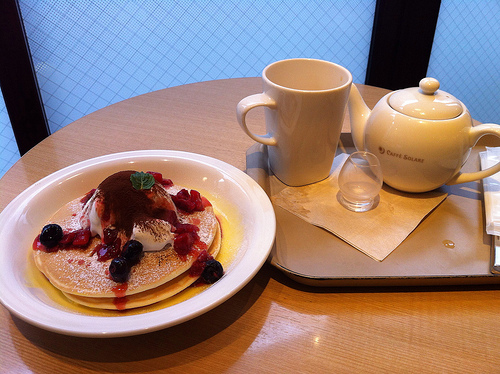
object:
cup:
[236, 58, 352, 186]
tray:
[243, 130, 499, 287]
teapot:
[348, 77, 499, 192]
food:
[29, 170, 245, 317]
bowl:
[0, 149, 276, 338]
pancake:
[30, 186, 219, 310]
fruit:
[198, 252, 208, 261]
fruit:
[108, 258, 130, 282]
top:
[388, 77, 462, 120]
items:
[146, 53, 475, 232]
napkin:
[270, 153, 448, 262]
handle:
[235, 92, 277, 145]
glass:
[337, 151, 384, 213]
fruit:
[121, 239, 143, 260]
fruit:
[73, 233, 89, 245]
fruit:
[40, 224, 63, 249]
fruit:
[171, 188, 203, 211]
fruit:
[173, 233, 194, 255]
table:
[0, 76, 499, 373]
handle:
[447, 123, 500, 186]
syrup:
[32, 170, 210, 310]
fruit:
[202, 259, 224, 285]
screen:
[1, 1, 500, 180]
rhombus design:
[118, 27, 134, 43]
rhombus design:
[190, 20, 203, 35]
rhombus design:
[253, 28, 267, 41]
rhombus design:
[296, 38, 310, 52]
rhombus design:
[165, 47, 179, 61]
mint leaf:
[130, 171, 156, 190]